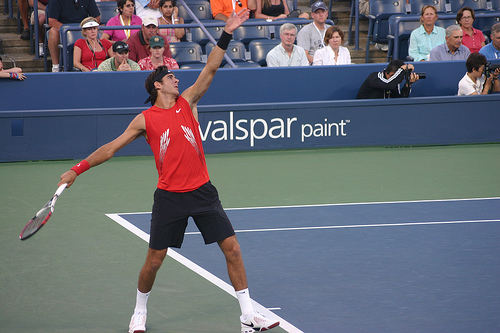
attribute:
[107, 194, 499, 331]
tennis court — blue, green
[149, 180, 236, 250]
shorts — black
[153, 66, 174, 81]
head band — black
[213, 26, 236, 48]
arm band — black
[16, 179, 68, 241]
tennis racket — white, black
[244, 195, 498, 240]
line — white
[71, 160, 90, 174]
armband — red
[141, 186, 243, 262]
shorts — black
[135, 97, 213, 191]
shirt — red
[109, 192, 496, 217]
line — white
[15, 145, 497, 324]
court — green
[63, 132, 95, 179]
wrist band — red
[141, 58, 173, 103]
sweatband — black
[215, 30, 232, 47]
arm band — black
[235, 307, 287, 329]
shoe — white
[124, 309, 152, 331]
shoe — white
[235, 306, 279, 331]
shoes — white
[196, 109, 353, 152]
letters — white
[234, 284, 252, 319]
socks — white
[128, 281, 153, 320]
socks — white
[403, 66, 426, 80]
camera — black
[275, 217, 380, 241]
lines — white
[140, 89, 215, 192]
tank top — red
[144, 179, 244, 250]
shorts — black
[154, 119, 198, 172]
design — white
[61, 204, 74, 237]
handle — white